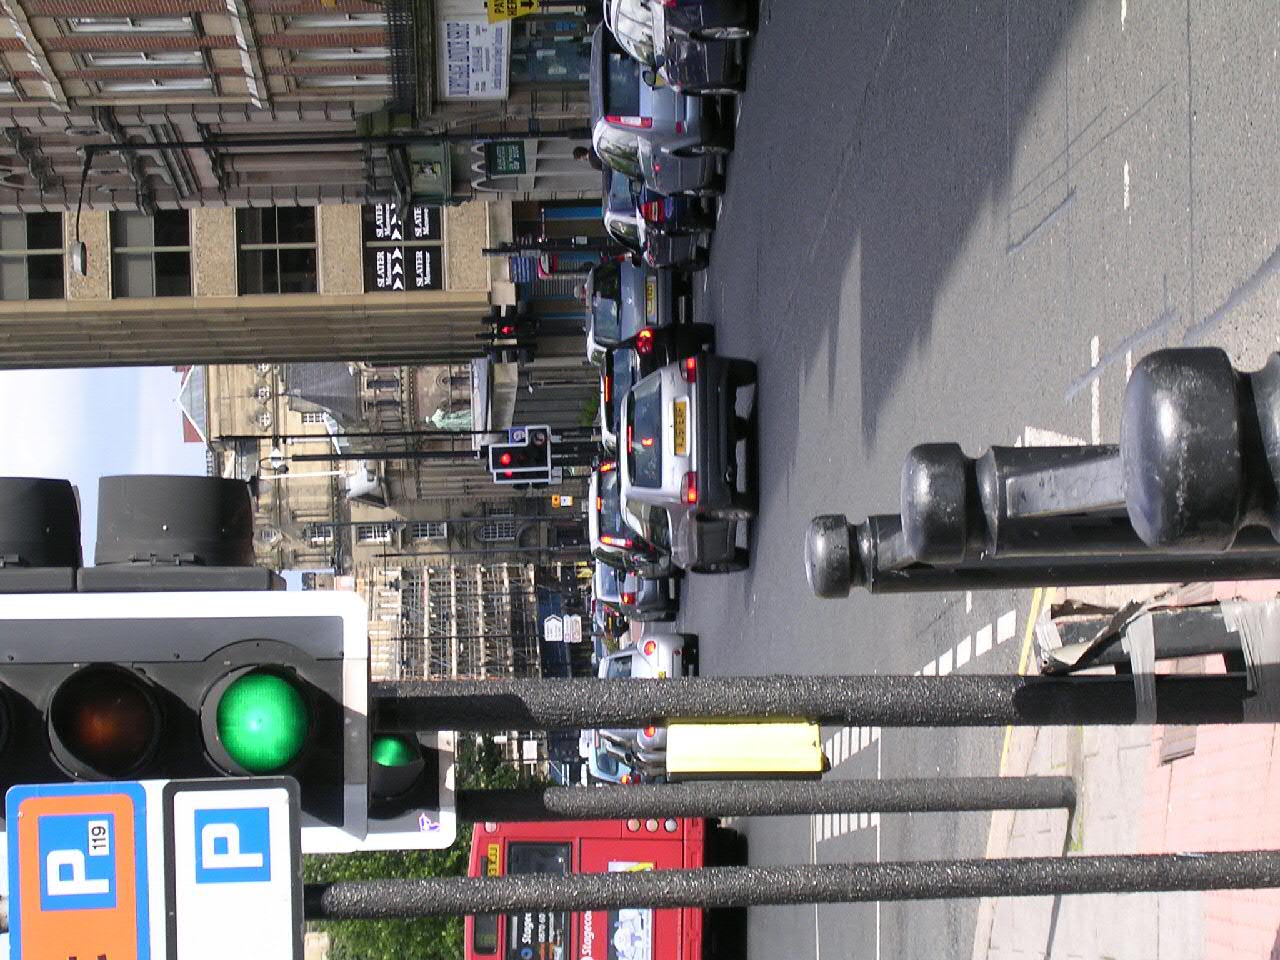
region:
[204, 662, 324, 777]
traffic light shining green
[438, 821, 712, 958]
back of a red bus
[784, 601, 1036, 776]
white dotted line on the ground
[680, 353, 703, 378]
red light on the back of the car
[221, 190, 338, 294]
window on the side of the building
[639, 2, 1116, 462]
shadows on the ground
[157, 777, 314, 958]
blue and white sign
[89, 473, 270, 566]
black cone around the light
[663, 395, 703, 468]
yellow and black license plate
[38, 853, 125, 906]
a P that is white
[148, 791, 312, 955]
a sign that is white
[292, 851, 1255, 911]
a pole that is dark grey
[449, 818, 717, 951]
a bus that is red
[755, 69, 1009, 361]
a shadow on the street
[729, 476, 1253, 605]
a black post on the street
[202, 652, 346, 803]
Green signal light is on.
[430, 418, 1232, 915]
Poles are black color.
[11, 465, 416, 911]
Signal light is black and white color.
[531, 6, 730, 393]
Cars are parked on sides of the road.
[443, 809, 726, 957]
Bus is red color.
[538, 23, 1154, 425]
Shadow falls on the road.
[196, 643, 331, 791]
the light is green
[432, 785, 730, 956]
the bus is color red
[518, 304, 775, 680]
car in the road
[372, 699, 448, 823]
the light is green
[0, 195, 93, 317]
the window of a building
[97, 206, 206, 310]
the window of a building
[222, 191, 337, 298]
the window of a building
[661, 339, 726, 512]
red lights on back the car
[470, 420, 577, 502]
the traffic lights on red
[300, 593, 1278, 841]
the pole of a traffic light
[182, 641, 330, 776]
a green traffic light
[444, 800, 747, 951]
a red bus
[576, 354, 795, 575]
a white car with yellow tags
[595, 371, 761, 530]
a vehicle on the road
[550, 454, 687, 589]
a vehicle on the road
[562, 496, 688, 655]
a vehicle on the road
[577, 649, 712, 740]
a vehicle on the road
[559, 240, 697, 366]
a vehicle on the road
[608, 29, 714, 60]
a vehicle on the road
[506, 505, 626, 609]
a vehicle on the road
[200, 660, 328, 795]
Street light is green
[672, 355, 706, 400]
Taillight of a car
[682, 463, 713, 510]
Taillight of a car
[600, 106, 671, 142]
Taillight of a car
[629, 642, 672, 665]
Taillight of a car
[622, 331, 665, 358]
Taillight of a car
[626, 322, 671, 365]
Taillight of a black car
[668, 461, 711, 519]
Taillight of a silver car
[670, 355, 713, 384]
Taillight of a silver car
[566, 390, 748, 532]
a car on the road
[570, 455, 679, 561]
a car on the road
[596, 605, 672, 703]
a car on the road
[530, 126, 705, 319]
a car on the road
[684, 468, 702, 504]
red tail light on car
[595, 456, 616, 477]
red tail light on car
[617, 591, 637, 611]
red tail light on car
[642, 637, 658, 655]
red tail light on car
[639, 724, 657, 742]
red tail light on car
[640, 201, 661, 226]
red tail light on car